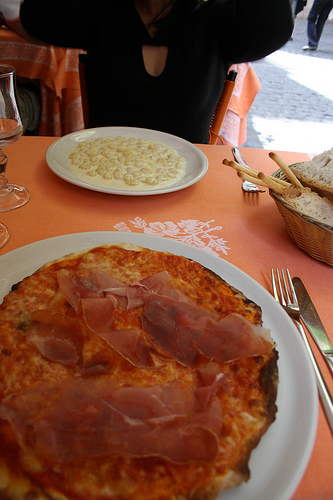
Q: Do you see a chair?
A: Yes, there is a chair.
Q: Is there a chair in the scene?
A: Yes, there is a chair.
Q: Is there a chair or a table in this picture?
A: Yes, there is a chair.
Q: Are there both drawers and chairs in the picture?
A: No, there is a chair but no drawers.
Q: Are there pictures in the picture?
A: No, there are no pictures.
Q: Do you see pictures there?
A: No, there are no pictures.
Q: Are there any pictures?
A: No, there are no pictures.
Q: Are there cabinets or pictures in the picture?
A: No, there are no pictures or cabinets.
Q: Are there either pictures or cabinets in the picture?
A: No, there are no pictures or cabinets.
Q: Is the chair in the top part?
A: Yes, the chair is in the top of the image.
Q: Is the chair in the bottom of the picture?
A: No, the chair is in the top of the image.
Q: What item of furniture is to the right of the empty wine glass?
A: The piece of furniture is a chair.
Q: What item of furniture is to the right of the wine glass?
A: The piece of furniture is a chair.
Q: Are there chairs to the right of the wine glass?
A: Yes, there is a chair to the right of the wine glass.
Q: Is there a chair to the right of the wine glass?
A: Yes, there is a chair to the right of the wine glass.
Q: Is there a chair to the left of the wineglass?
A: No, the chair is to the right of the wineglass.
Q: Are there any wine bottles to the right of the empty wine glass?
A: No, there is a chair to the right of the wineglass.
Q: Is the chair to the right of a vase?
A: No, the chair is to the right of a wine glass.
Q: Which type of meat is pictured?
A: The meat is ham.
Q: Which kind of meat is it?
A: The meat is ham.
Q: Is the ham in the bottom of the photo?
A: Yes, the ham is in the bottom of the image.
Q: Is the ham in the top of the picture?
A: No, the ham is in the bottom of the image.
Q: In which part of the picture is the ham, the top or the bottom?
A: The ham is in the bottom of the image.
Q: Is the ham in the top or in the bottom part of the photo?
A: The ham is in the bottom of the image.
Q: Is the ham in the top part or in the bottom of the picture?
A: The ham is in the bottom of the image.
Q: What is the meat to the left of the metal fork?
A: The meat is ham.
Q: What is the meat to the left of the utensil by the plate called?
A: The meat is ham.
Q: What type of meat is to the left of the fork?
A: The meat is ham.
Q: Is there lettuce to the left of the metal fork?
A: No, there is ham to the left of the fork.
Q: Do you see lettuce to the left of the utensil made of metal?
A: No, there is ham to the left of the fork.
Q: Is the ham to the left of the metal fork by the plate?
A: Yes, the ham is to the left of the fork.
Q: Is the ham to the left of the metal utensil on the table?
A: Yes, the ham is to the left of the fork.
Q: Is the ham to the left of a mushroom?
A: No, the ham is to the left of the fork.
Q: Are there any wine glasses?
A: Yes, there is a wine glass.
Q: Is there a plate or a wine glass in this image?
A: Yes, there is a wine glass.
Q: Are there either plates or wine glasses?
A: Yes, there is a wine glass.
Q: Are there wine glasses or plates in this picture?
A: Yes, there is a wine glass.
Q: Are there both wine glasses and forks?
A: Yes, there are both a wine glass and a fork.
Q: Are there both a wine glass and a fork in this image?
A: Yes, there are both a wine glass and a fork.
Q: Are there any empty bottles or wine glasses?
A: Yes, there is an empty wine glass.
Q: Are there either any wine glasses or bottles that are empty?
A: Yes, the wine glass is empty.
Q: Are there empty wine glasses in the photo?
A: Yes, there is an empty wine glass.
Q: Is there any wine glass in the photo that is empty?
A: Yes, there is a wine glass that is empty.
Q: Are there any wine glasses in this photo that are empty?
A: Yes, there is a wine glass that is empty.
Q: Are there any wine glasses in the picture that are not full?
A: Yes, there is a empty wine glass.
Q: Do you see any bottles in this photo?
A: No, there are no bottles.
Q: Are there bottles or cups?
A: No, there are no bottles or cups.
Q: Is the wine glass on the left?
A: Yes, the wine glass is on the left of the image.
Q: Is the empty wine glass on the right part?
A: No, the wineglass is on the left of the image.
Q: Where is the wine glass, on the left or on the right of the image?
A: The wine glass is on the left of the image.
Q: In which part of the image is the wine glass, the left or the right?
A: The wine glass is on the left of the image.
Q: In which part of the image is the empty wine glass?
A: The wineglass is on the left of the image.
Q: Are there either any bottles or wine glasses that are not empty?
A: No, there is a wine glass but it is empty.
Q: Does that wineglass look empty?
A: Yes, the wineglass is empty.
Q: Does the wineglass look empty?
A: Yes, the wineglass is empty.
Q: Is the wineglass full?
A: No, the wineglass is empty.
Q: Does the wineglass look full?
A: No, the wineglass is empty.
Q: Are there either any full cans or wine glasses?
A: No, there is a wine glass but it is empty.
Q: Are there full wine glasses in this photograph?
A: No, there is a wine glass but it is empty.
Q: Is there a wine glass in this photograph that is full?
A: No, there is a wine glass but it is empty.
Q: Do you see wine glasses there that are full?
A: No, there is a wine glass but it is empty.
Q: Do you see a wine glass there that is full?
A: No, there is a wine glass but it is empty.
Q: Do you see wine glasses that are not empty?
A: No, there is a wine glass but it is empty.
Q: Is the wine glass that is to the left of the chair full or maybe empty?
A: The wine glass is empty.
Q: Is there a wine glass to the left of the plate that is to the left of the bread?
A: Yes, there is a wine glass to the left of the plate.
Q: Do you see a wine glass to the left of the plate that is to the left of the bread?
A: Yes, there is a wine glass to the left of the plate.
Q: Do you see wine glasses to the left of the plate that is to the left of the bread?
A: Yes, there is a wine glass to the left of the plate.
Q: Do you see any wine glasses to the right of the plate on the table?
A: No, the wine glass is to the left of the plate.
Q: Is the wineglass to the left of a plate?
A: Yes, the wineglass is to the left of a plate.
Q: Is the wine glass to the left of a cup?
A: No, the wine glass is to the left of a plate.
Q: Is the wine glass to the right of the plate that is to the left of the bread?
A: No, the wine glass is to the left of the plate.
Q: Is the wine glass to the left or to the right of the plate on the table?
A: The wine glass is to the left of the plate.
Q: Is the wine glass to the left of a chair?
A: Yes, the wine glass is to the left of a chair.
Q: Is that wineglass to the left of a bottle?
A: No, the wineglass is to the left of a chair.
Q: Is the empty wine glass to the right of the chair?
A: No, the wine glass is to the left of the chair.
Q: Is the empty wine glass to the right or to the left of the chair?
A: The wine glass is to the left of the chair.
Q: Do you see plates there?
A: Yes, there is a plate.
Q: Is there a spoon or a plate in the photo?
A: Yes, there is a plate.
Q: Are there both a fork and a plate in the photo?
A: Yes, there are both a plate and a fork.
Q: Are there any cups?
A: No, there are no cups.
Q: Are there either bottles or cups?
A: No, there are no cups or bottles.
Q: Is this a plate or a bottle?
A: This is a plate.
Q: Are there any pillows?
A: No, there are no pillows.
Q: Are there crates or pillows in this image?
A: No, there are no pillows or crates.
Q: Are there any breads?
A: Yes, there is a bread.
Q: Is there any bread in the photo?
A: Yes, there is a bread.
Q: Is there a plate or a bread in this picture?
A: Yes, there is a bread.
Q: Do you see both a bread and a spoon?
A: No, there is a bread but no spoons.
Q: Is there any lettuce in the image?
A: No, there is no lettuce.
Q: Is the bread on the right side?
A: Yes, the bread is on the right of the image.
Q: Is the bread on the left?
A: No, the bread is on the right of the image.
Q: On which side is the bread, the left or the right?
A: The bread is on the right of the image.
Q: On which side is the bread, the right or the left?
A: The bread is on the right of the image.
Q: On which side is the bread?
A: The bread is on the right of the image.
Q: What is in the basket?
A: The bread is in the basket.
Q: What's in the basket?
A: The bread is in the basket.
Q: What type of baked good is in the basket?
A: The food is a bread.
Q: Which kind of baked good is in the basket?
A: The food is a bread.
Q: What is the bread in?
A: The bread is in the basket.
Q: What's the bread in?
A: The bread is in the basket.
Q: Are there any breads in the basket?
A: Yes, there is a bread in the basket.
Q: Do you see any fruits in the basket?
A: No, there is a bread in the basket.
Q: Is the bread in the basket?
A: Yes, the bread is in the basket.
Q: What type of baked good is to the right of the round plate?
A: The food is a bread.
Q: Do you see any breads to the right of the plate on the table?
A: Yes, there is a bread to the right of the plate.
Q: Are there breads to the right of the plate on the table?
A: Yes, there is a bread to the right of the plate.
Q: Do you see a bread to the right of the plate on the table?
A: Yes, there is a bread to the right of the plate.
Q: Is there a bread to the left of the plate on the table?
A: No, the bread is to the right of the plate.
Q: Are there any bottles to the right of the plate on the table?
A: No, there is a bread to the right of the plate.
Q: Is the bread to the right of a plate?
A: Yes, the bread is to the right of a plate.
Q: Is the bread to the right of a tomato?
A: No, the bread is to the right of a plate.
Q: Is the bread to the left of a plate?
A: No, the bread is to the right of a plate.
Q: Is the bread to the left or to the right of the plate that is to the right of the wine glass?
A: The bread is to the right of the plate.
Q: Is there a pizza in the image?
A: Yes, there is a pizza.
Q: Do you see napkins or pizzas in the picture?
A: Yes, there is a pizza.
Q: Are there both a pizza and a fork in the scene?
A: Yes, there are both a pizza and a fork.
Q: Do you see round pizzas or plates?
A: Yes, there is a round pizza.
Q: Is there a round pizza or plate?
A: Yes, there is a round pizza.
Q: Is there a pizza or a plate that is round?
A: Yes, the pizza is round.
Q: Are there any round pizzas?
A: Yes, there is a round pizza.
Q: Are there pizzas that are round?
A: Yes, there is a pizza that is round.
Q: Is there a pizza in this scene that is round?
A: Yes, there is a pizza that is round.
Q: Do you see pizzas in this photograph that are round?
A: Yes, there is a pizza that is round.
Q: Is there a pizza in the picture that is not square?
A: Yes, there is a round pizza.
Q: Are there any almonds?
A: No, there are no almonds.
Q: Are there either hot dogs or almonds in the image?
A: No, there are no almonds or hot dogs.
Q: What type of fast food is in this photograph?
A: The fast food is a pizza.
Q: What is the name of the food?
A: The food is a pizza.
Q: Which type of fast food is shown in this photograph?
A: The fast food is a pizza.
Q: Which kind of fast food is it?
A: The food is a pizza.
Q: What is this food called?
A: That is a pizza.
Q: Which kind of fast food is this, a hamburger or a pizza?
A: That is a pizza.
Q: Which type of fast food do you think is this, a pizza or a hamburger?
A: That is a pizza.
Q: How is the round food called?
A: The food is a pizza.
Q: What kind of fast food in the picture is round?
A: The fast food is a pizza.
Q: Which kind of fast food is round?
A: The fast food is a pizza.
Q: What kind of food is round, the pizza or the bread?
A: The pizza is round.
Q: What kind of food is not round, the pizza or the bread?
A: The bread is not round.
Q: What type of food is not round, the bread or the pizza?
A: The bread is not round.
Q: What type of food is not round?
A: The food is a bread.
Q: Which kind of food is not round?
A: The food is a bread.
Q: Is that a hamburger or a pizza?
A: That is a pizza.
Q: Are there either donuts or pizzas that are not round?
A: No, there is a pizza but it is round.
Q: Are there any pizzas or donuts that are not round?
A: No, there is a pizza but it is round.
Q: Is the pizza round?
A: Yes, the pizza is round.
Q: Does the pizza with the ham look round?
A: Yes, the pizza is round.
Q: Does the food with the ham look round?
A: Yes, the pizza is round.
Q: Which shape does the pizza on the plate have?
A: The pizza has round shape.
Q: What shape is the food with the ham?
A: The pizza is round.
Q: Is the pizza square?
A: No, the pizza is round.